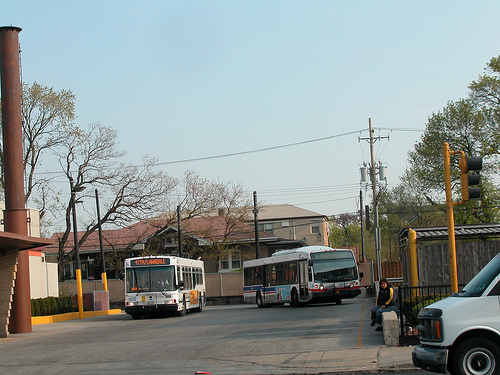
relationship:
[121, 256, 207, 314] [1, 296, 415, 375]
bus on side of road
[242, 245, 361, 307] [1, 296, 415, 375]
bus driving on road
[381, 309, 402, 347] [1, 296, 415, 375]
barrier beside road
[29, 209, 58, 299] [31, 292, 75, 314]
building behind hedges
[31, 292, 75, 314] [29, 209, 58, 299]
hedges next to building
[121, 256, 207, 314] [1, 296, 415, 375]
bus parked in road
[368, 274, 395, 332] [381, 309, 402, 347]
woman sitting on barrier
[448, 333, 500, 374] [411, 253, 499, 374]
tire on van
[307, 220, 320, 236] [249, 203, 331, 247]
window on building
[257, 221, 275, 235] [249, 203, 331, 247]
window on building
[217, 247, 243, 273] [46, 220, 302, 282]
window on building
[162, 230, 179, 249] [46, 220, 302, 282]
window on building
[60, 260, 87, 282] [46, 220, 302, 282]
window on building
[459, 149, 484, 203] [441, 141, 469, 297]
stoplight on pole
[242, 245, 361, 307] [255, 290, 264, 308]
bus has back-wheel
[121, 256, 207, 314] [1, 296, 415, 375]
bus in road